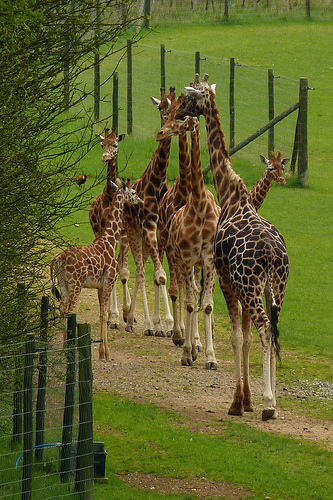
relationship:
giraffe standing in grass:
[174, 72, 290, 420] [16, 14, 331, 378]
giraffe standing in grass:
[154, 93, 222, 373] [16, 14, 331, 378]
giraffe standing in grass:
[113, 85, 181, 335] [16, 14, 331, 378]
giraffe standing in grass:
[50, 178, 145, 366] [0, 374, 332, 498]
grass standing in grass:
[0, 374, 332, 498] [16, 14, 331, 378]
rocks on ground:
[281, 376, 331, 398] [51, 285, 329, 498]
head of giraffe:
[95, 128, 126, 163] [86, 127, 135, 326]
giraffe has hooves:
[174, 72, 290, 420] [223, 384, 280, 422]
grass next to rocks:
[46, 375, 331, 498] [274, 372, 332, 410]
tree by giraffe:
[1, 0, 161, 437] [50, 178, 145, 366]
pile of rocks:
[289, 377, 331, 402] [287, 373, 332, 398]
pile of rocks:
[289, 377, 331, 402] [191, 375, 230, 389]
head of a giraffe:
[96, 129, 126, 162] [86, 127, 135, 326]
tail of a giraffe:
[263, 244, 282, 366] [174, 72, 290, 420]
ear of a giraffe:
[185, 87, 200, 100] [174, 72, 290, 420]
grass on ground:
[92, 388, 333, 500] [6, 1, 332, 496]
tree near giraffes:
[1, 0, 161, 437] [153, 73, 298, 368]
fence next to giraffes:
[1, 338, 111, 498] [141, 76, 300, 335]